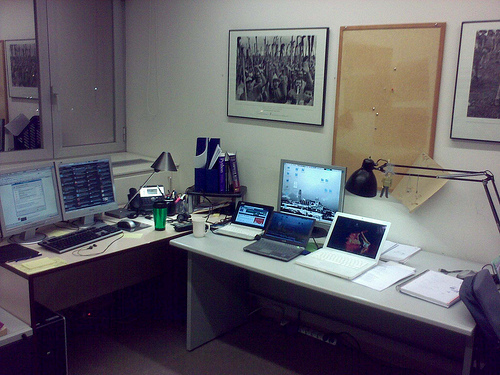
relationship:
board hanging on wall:
[330, 21, 446, 192] [123, 5, 495, 263]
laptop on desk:
[296, 212, 393, 283] [169, 211, 495, 369]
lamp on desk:
[345, 157, 498, 227] [169, 211, 495, 369]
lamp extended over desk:
[345, 157, 498, 227] [169, 211, 495, 369]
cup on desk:
[151, 199, 167, 232] [1, 204, 189, 370]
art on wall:
[221, 26, 329, 128] [123, 5, 495, 263]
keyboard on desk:
[39, 221, 124, 252] [1, 204, 189, 370]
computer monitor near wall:
[275, 158, 345, 230] [123, 5, 495, 263]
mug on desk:
[189, 213, 210, 235] [169, 211, 495, 369]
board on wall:
[330, 21, 446, 192] [123, 5, 495, 263]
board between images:
[330, 21, 446, 192] [218, 18, 497, 147]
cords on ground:
[242, 294, 389, 372] [57, 271, 442, 373]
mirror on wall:
[0, 2, 117, 151] [1, 0, 164, 213]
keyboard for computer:
[39, 221, 124, 252] [3, 152, 120, 247]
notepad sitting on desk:
[395, 268, 464, 314] [169, 211, 495, 369]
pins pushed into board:
[369, 65, 399, 133] [330, 21, 446, 192]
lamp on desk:
[104, 151, 177, 220] [1, 204, 189, 370]